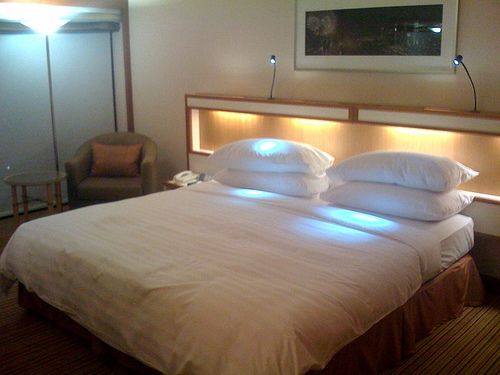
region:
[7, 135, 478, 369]
a large, clean bed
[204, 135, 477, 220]
pillow stacked on the bed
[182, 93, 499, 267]
headboard of the bed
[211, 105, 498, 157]
lights in the headboard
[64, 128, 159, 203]
a chair next to the bed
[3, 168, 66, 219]
a small table next to the chair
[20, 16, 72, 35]
a light above the chair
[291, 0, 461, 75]
a picture hanging above the bed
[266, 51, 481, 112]
book lights above the headboard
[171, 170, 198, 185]
a telephone next to the bed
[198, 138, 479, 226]
four white pillows on a bed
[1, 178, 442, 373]
white comforter on a bed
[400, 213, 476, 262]
white sheet on a bed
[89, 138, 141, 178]
brown pillow in an arm chair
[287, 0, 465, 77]
artwork on a wall over a bed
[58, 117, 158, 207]
green arm chair in a corner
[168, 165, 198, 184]
white telephone next to a bed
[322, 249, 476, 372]
brown bed skirt on a white bed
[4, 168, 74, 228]
small table next to an arm chair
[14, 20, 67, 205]
tall, skinny floor lamp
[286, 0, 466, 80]
A framed picture hanging on a wall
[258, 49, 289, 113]
A small light on a table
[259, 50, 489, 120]
Two small lights on a table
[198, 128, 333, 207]
Two white pillows on a bed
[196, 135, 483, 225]
Four white pillows on a bed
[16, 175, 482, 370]
A Bed spread on a bed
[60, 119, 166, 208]
A chair in the corner of a room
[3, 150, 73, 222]
A small table near a wall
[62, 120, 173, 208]
A brown pillow on a chair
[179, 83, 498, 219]
A lighted head board in a bedroom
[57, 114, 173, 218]
Small squat greenish chair with a large light brown pillow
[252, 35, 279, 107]
Long thin black light fixture with a blue colored light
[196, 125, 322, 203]
Two white pillows piled on top of each other with blue lighting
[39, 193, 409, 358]
White sheet covering a bed with pale stripes running across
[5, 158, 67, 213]
Small brown table with a circular top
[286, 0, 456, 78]
Dark colored picture on the wall in a large white frame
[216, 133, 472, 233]
Stack of four white pillows at the head of a bed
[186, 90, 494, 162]
Head of a bed receded into a white wall with wooden panelling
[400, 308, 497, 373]
Striped multi colored rug with gray, brown, and black stripes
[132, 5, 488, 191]
White wall behind a bed with a painting and lights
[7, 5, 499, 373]
A bedroom.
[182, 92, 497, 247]
A headboard with lights.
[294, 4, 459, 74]
A rectangular picture on the wall.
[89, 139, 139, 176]
A brown pillow.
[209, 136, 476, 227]
White pillows at the top of the bed.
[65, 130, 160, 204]
A beige colored armchair.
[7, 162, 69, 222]
A small round side table.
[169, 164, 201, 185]
A white telephone.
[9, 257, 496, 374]
A brown bedskirt.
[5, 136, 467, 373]
White bedding.